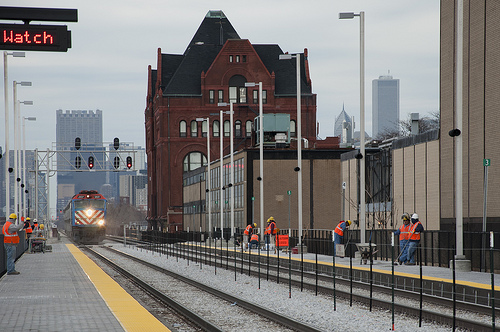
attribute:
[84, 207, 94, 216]
light — on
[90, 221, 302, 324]
rails — metallic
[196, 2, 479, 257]
poles — tall, utility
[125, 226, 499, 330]
poles — black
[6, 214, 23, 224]
helmet — yellow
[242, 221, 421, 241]
vests — orange 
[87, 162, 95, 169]
red signal — Red 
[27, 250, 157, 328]
platform — yellow 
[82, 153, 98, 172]
signal — horizontal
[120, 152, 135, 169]
signal — horizontal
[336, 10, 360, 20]
fixtures — street, light